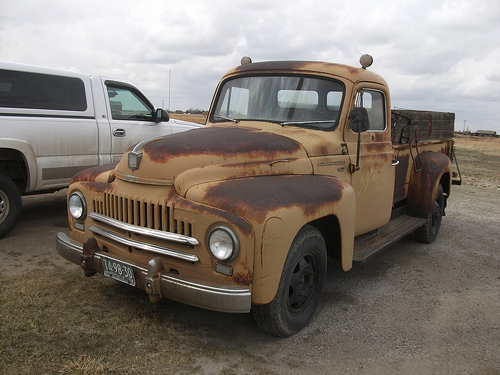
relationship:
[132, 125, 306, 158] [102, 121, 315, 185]
mark on hood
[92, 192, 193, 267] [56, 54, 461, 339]
grill on car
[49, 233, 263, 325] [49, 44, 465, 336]
bumper on car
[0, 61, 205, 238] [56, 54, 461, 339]
car next to car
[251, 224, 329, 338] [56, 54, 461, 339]
tire of car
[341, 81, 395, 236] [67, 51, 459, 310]
door of truck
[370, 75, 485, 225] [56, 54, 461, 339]
bed to car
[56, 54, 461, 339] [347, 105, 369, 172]
car has mirror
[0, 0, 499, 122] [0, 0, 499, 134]
cloud are on sky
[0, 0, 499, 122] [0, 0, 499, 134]
cloud on sky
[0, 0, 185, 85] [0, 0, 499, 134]
cloud on sky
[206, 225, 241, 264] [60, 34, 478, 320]
headlight on front of truck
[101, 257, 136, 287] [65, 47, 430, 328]
license plate on front of truck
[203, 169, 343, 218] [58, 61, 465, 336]
spot on truck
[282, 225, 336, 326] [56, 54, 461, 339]
tire on front of car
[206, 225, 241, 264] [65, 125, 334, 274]
headlight on hood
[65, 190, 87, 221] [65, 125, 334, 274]
headlight on hood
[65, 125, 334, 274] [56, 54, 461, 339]
hood on car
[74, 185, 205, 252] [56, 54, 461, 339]
grill on front of car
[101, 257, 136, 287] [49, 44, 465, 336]
license plate on front of car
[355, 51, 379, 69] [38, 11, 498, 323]
light on top of car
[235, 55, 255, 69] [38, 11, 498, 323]
light on top of car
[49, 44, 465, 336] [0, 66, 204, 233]
car next to car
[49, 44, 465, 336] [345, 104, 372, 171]
car has mirror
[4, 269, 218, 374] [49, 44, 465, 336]
grass under car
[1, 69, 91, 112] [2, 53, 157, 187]
window on car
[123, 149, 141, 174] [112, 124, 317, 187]
light on hood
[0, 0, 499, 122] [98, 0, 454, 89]
cloud in sky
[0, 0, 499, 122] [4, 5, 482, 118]
cloud in sky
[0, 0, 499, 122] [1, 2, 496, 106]
cloud in sky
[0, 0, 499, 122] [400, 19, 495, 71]
cloud in sky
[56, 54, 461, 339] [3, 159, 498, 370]
car parked on ground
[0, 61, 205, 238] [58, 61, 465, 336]
car parked next to truck